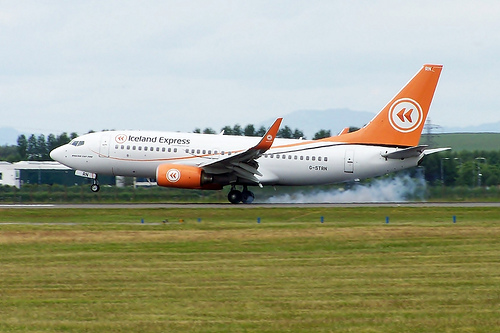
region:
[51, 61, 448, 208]
an orange and white plane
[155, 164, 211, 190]
an orange plane engine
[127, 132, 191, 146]
black lettering on a plane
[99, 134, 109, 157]
door on a plane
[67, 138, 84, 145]
cockpit windows of a plane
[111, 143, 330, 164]
passenger windows on a plane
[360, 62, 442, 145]
the tail of a plane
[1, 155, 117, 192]
a building in the distance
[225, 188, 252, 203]
wheels on a plane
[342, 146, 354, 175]
door on a plane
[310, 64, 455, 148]
Orange tail wing of the plane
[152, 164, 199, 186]
Orange jet of the plane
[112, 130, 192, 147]
Iceland Express logo on the side of the plane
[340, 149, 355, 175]
White door at the back of the plane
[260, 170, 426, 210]
Smoke underneath the plane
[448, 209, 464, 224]
Blue marker in the grass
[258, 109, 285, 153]
Orange and white wing tip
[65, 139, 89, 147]
Windows at the front of the plane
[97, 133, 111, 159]
White door of the plane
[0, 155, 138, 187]
White building behind the plane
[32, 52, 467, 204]
An orange and white airplane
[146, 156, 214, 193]
An orange engine on an airplane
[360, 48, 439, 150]
An orange tail on an airplane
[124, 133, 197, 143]
Words that say Iceland Express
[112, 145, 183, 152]
Windows on an airplane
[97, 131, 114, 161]
A door on an airplane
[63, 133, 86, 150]
Windshield on an airplane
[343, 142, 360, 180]
the back door on an airplane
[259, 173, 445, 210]
Smoke under the airplane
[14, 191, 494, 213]
The runway at an airport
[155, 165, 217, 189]
the engine of a plane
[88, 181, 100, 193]
front wheel of a plane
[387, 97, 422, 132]
circular logo on a plane tail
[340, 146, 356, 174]
door at the rear of a plane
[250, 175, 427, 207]
smoke from a plane's wheels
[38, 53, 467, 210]
a plane landing in the daytime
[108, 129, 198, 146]
brand name of the airline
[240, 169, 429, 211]
smoke from tire friction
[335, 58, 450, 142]
tail fin on the plance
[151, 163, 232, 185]
jet engine on a wing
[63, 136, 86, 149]
windshield of the pilot's cabin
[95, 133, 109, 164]
front passenger entrance door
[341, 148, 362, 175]
rear door of the plane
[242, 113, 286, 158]
end of the wing turned up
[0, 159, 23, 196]
building near the runway